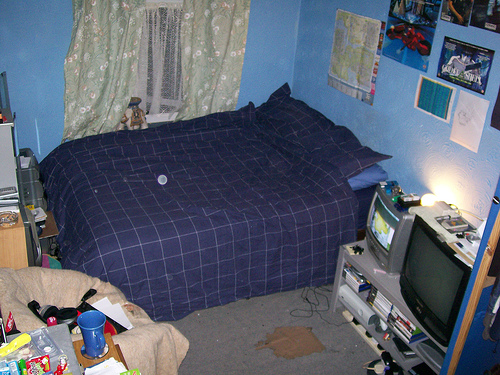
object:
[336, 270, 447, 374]
game system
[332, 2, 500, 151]
posters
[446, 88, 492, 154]
papers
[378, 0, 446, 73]
pictures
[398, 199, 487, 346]
tv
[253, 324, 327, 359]
stain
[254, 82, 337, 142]
case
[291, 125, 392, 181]
case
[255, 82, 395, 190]
pillow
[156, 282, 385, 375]
floor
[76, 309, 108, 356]
blue cup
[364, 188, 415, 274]
televisions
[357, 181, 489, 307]
electronics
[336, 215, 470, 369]
table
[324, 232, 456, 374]
stand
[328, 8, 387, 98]
map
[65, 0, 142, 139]
curtain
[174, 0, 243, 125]
curtain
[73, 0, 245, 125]
window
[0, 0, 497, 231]
wall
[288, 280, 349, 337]
wires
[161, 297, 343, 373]
carpet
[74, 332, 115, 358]
cd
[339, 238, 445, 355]
shelf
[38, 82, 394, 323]
bed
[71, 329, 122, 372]
table